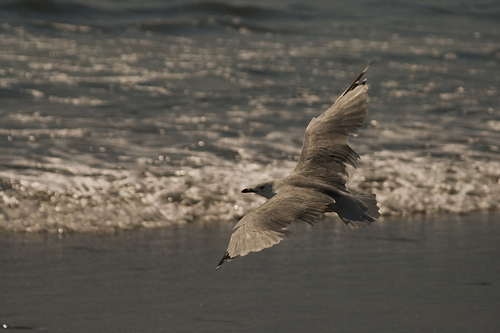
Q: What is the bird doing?
A: Flying.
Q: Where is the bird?
A: Sky.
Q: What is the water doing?
A: Rolling.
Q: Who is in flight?
A: A bird.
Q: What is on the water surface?
A: Ripples.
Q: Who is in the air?
A: A bird.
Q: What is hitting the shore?
A: Foam of the water.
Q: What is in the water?
A: Wave.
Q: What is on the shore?
A: Sand.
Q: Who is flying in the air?
A: The bird.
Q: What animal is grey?
A: The bird.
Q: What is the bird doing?
A: Flying.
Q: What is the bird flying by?
A: The ocean.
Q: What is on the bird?
A: Feathers.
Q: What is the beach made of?
A: Sand.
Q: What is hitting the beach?
A: A wave.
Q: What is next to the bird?
A: Water.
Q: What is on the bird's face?
A: A beak.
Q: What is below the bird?
A: The beach.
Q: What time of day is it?
A: Early evening.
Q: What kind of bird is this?
A: Seagull.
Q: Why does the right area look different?
A: It's shore.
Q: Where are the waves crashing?
A: Shoreline.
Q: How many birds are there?
A: One.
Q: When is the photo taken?
A: During the day.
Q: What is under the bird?
A: The beach.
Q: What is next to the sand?
A: The water.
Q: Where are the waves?
A: In the ocean.